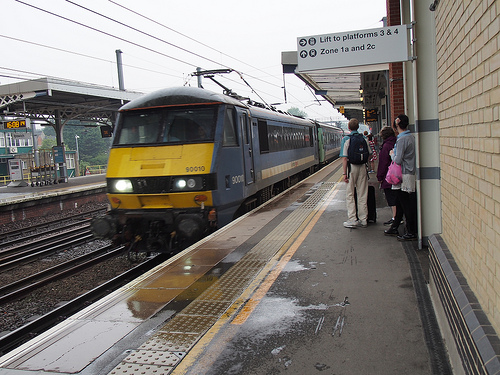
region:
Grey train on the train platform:
[87, 84, 343, 263]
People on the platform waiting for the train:
[337, 113, 421, 243]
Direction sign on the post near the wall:
[291, 21, 414, 76]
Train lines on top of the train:
[0, 1, 325, 109]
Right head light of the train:
[103, 175, 136, 195]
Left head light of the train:
[166, 170, 203, 190]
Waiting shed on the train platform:
[0, 75, 146, 188]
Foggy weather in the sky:
[1, 0, 391, 125]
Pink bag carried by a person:
[383, 161, 406, 186]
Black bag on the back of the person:
[345, 131, 370, 165]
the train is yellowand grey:
[83, 98, 297, 252]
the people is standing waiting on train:
[338, 107, 420, 228]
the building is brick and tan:
[442, 142, 499, 253]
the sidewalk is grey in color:
[278, 270, 435, 373]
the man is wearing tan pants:
[338, 166, 389, 233]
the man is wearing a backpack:
[347, 138, 374, 173]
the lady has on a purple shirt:
[380, 144, 394, 194]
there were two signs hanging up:
[287, 34, 425, 76]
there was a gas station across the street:
[14, 128, 102, 192]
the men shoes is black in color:
[385, 222, 422, 247]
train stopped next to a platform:
[87, 85, 349, 261]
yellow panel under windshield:
[103, 142, 212, 176]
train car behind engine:
[317, 123, 347, 164]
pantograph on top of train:
[190, 65, 282, 110]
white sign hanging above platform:
[296, 23, 410, 76]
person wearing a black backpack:
[337, 118, 376, 228]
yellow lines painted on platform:
[171, 174, 342, 374]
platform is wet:
[1, 151, 446, 373]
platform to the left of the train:
[3, 170, 117, 204]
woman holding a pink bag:
[380, 113, 417, 240]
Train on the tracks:
[99, 87, 354, 252]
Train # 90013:
[181, 161, 211, 173]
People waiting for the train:
[331, 105, 419, 248]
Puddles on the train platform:
[40, 158, 345, 370]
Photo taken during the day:
[7, 9, 492, 366]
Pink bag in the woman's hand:
[379, 160, 404, 186]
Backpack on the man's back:
[348, 124, 375, 168]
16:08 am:
[0, 120, 32, 128]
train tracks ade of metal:
[10, 223, 132, 337]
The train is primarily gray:
[209, 90, 345, 206]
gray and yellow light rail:
[101, 88, 279, 229]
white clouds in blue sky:
[42, 21, 103, 85]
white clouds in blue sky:
[210, 6, 251, 50]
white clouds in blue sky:
[134, 9, 186, 51]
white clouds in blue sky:
[47, 22, 82, 54]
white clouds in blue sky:
[238, 19, 272, 69]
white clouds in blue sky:
[161, 31, 222, 61]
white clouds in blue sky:
[64, 11, 94, 41]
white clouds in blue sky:
[140, 22, 177, 62]